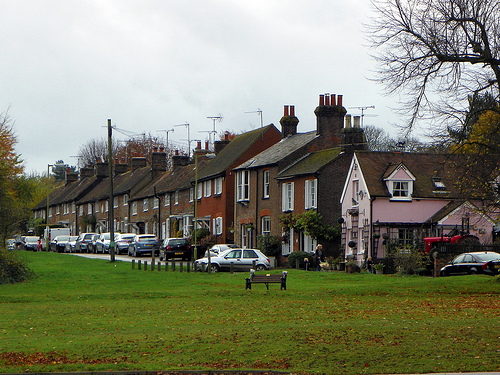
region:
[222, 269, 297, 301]
a wood bench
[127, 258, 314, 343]
a wood bench in field of grass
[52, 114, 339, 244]
several buildings in a row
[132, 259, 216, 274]
small wood post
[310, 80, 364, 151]
a chimney on the roof of a building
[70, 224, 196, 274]
a row of cars parked next to the curb of a street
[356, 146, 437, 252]
a pink house with a shingled roof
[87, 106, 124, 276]
a wood electrical pole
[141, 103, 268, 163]
several antenna on roofs of buildings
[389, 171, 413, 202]
white curtains hanging in a window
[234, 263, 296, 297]
Empty park bench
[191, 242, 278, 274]
Silver hatch-back 4 door car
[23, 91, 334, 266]
Brownstown houses on street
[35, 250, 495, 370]
field of green grass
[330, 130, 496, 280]
Pink house with dog-house dormers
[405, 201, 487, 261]
Red tractor in the yard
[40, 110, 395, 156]
Telephone poles and antennas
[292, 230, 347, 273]
Woman working outside house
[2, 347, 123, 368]
Pile of autumn leaves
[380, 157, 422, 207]
Pink dog-house dormer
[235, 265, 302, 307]
a wood bench in a field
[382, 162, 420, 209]
white curtains in a window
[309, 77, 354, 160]
a chimney on a roof of a building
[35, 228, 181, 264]
a row of vehicles parked in front of buildings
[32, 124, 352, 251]
a row of buildings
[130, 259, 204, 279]
short wood post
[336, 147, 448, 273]
a pink house with white trim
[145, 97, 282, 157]
a row of antenna's on the roofs of buildings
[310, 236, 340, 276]
a person in front of a building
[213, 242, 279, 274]
the car is silver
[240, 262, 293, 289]
the bench is wooden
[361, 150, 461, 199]
the roof is brown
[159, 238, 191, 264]
the car is blue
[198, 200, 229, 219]
the wall is red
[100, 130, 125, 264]
the pole is wooden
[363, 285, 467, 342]
the leaves are brown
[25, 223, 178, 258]
the cars are parked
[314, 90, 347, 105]
the chimney is red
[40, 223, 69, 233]
the van is white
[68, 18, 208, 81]
sky above the buildings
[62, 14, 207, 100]
clouds in the sky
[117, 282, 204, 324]
grass on the ground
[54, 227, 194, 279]
cars parked near each other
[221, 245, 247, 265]
window of the car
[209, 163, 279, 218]
windows on the houses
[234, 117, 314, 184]
top of the house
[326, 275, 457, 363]
leaves on the grass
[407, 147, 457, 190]
brown roof of house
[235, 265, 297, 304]
bench in the grass